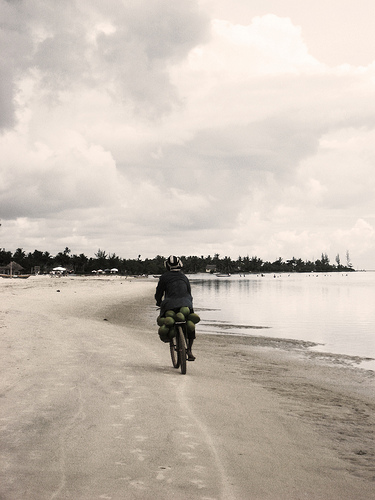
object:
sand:
[0, 271, 374, 500]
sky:
[0, 1, 374, 254]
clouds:
[0, 1, 374, 259]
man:
[153, 253, 201, 362]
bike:
[170, 323, 190, 375]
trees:
[333, 252, 344, 270]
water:
[176, 270, 374, 368]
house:
[50, 265, 67, 278]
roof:
[53, 265, 68, 271]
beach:
[1, 261, 374, 343]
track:
[166, 383, 233, 499]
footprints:
[125, 476, 146, 496]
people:
[240, 273, 246, 278]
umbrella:
[110, 266, 118, 273]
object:
[54, 287, 65, 295]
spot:
[52, 280, 65, 298]